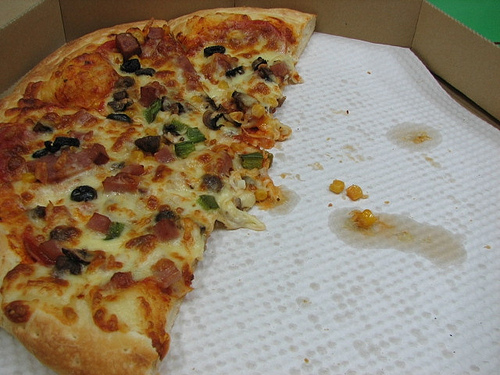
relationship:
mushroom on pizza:
[56, 245, 96, 273] [0, 0, 316, 374]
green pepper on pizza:
[195, 192, 220, 214] [27, 27, 314, 311]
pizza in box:
[0, 0, 316, 374] [1, 0, 498, 372]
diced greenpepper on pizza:
[242, 155, 263, 166] [0, 0, 316, 374]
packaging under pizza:
[3, 32, 497, 372] [0, 0, 316, 374]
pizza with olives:
[0, 0, 316, 374] [31, 133, 86, 165]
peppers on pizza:
[154, 108, 275, 217] [5, 15, 346, 373]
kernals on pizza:
[98, 49, 221, 158] [86, 72, 180, 173]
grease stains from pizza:
[332, 172, 432, 307] [327, 110, 483, 290]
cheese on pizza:
[90, 227, 120, 255] [0, 0, 316, 374]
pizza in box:
[0, 0, 316, 374] [412, 19, 497, 119]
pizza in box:
[10, 38, 219, 355] [390, 5, 484, 117]